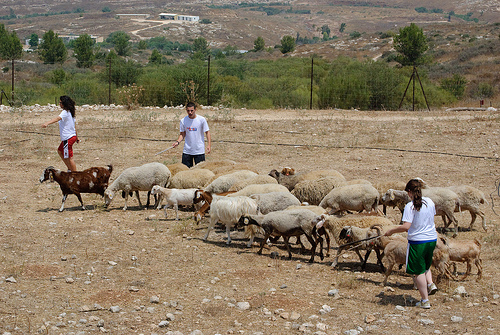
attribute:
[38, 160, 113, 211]
sheep — brown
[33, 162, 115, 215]
goat — brown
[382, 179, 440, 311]
woman — standing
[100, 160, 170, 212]
sheep — white 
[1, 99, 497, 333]
field — sandy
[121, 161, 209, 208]
sheep — white 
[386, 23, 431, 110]
tree — green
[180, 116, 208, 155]
t-shirt — white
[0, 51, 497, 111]
fencing — metal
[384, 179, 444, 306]
woman — herding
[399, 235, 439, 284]
shorts — green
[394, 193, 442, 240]
t-shirt — white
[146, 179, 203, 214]
goat — white, small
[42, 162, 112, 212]
goat — brown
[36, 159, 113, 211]
goat — brown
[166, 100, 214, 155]
man — herding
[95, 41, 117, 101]
tree — green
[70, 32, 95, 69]
tree — green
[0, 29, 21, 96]
tree — green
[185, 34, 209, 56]
tree — green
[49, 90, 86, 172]
woman — herding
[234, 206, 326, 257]
sheep — white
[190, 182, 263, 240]
sheep — white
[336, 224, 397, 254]
sheep — white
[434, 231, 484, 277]
sheep — white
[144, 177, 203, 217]
sheep — white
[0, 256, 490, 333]
rocks — laying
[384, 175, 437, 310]
person — standing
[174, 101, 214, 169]
person — standing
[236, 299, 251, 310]
rock — small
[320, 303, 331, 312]
rock — small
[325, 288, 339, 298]
rock — small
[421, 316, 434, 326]
rock — small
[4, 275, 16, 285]
rock — small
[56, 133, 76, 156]
shorts — red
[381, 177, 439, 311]
person — young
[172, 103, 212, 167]
person — young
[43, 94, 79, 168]
person — standing, young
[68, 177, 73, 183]
spot — white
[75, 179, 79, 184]
spot — white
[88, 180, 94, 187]
spot — white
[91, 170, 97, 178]
spot — white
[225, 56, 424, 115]
brush — green